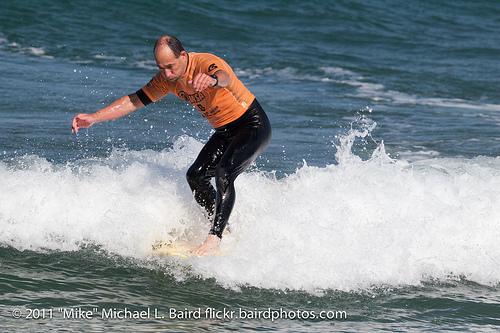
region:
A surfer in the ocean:
[2, 1, 496, 326]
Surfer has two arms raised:
[68, 29, 235, 136]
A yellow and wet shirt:
[130, 50, 258, 131]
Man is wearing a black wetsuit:
[131, 30, 275, 242]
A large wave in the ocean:
[1, 116, 499, 300]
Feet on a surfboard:
[153, 230, 227, 261]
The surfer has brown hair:
[147, 31, 189, 86]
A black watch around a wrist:
[205, 68, 224, 93]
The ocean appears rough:
[2, 1, 499, 331]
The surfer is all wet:
[68, 29, 276, 254]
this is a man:
[51, 45, 281, 253]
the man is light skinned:
[106, 100, 126, 114]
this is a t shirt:
[188, 88, 228, 128]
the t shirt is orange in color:
[201, 83, 238, 113]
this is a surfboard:
[156, 239, 199, 269]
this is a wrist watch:
[213, 70, 217, 97]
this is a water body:
[344, 38, 459, 121]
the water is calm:
[406, 10, 483, 107]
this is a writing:
[17, 295, 342, 331]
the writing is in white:
[18, 305, 355, 331]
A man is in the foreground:
[67, 20, 304, 265]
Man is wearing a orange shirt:
[118, 45, 263, 136]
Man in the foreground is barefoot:
[180, 220, 241, 265]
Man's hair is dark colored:
[150, 30, 190, 90]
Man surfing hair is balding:
[140, 28, 193, 86]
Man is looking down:
[145, 35, 192, 83]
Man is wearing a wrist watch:
[200, 66, 220, 91]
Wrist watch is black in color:
[202, 65, 222, 95]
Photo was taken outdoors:
[1, 3, 498, 328]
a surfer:
[56, 23, 346, 287]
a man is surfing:
[61, 23, 387, 281]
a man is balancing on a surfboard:
[57, 23, 426, 280]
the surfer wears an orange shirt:
[63, 20, 336, 291]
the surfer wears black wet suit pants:
[57, 35, 312, 293]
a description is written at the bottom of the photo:
[11, 296, 361, 331]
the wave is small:
[23, 120, 499, 271]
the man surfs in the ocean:
[20, 17, 467, 324]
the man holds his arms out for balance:
[66, 18, 300, 270]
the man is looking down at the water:
[46, 28, 298, 275]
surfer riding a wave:
[63, 30, 295, 247]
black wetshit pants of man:
[178, 120, 273, 235]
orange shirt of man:
[138, 60, 248, 128]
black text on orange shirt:
[168, 62, 242, 121]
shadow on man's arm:
[125, 85, 145, 112]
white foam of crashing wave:
[16, 133, 493, 280]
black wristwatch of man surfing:
[207, 70, 222, 88]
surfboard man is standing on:
[158, 234, 218, 266]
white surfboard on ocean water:
[148, 236, 215, 283]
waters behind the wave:
[15, 11, 495, 141]